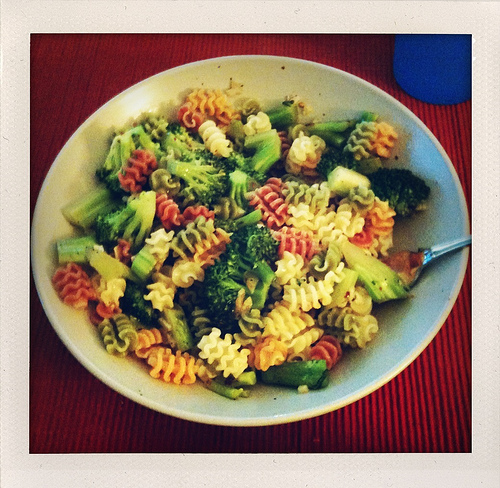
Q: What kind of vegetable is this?
A: Broccoli.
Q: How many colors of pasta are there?
A: Four.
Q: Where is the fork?
A: In the pasta.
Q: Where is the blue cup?
A: Near the plate.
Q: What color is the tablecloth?
A: Red.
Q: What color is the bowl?
A: White.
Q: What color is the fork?
A: Silver.